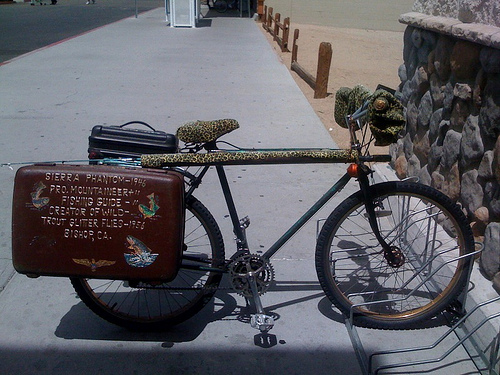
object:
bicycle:
[69, 86, 476, 332]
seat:
[177, 119, 240, 142]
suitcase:
[12, 163, 186, 285]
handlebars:
[335, 84, 390, 112]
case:
[87, 121, 178, 166]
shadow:
[55, 240, 462, 343]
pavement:
[241, 188, 302, 216]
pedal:
[250, 313, 275, 332]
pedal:
[239, 215, 250, 229]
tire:
[315, 181, 473, 329]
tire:
[69, 191, 225, 330]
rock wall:
[387, 24, 500, 293]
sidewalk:
[83, 37, 282, 113]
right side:
[4, 159, 473, 374]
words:
[41, 172, 146, 241]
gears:
[226, 253, 276, 297]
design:
[176, 119, 240, 143]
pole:
[314, 42, 333, 99]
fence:
[256, 2, 334, 99]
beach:
[344, 28, 396, 82]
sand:
[317, 15, 399, 43]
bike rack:
[315, 175, 499, 374]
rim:
[360, 306, 425, 321]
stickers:
[123, 235, 160, 268]